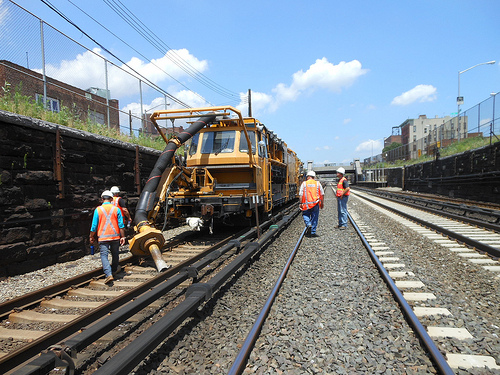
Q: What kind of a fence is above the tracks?
A: Wire fence.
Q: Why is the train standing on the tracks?
A: To be repaired.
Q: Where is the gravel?
A: Along train tracks.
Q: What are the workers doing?
A: Repairing the train.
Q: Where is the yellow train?
A: On the tracks.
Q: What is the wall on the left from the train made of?
A: Stone.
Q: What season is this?
A: Summer.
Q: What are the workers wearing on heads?
A: Safety helmets.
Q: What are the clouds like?
A: White and puffy.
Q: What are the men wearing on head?
A: Hard hats.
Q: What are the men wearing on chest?
A: Orange vest.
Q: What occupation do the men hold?
A: Railroad workers.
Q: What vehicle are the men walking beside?
A: Train.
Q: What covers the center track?
A: Gravel.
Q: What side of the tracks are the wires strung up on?
A: Left.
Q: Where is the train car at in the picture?
A: On tracks.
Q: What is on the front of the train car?
A: A hose.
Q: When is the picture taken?
A: Daytime.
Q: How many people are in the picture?
A: Three.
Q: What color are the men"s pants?
A: Blue jean.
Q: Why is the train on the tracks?
A: To move.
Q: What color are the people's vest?
A: Orange and white.